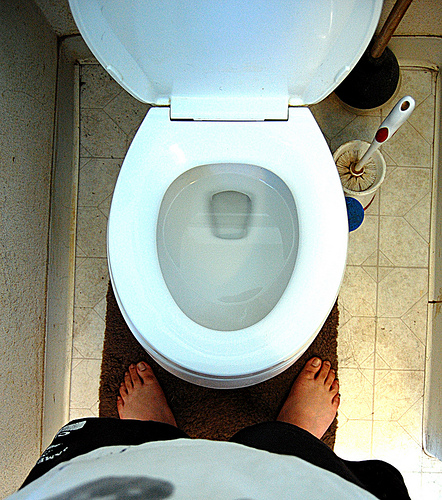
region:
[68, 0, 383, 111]
an uplifted toilet lid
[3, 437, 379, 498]
a white shirt on a person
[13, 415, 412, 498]
black shorts on a person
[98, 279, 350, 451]
a brown rug under a person's feet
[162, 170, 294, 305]
water in a toilet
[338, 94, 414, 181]
a scrub brush next to a toilet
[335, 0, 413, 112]
a plunger next to a toilet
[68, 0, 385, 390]
a white bathroom toilet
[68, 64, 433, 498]
a dirty linoleum bathroom floor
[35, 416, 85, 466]
white print on a pair of shorts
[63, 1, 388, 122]
A toilet lid is up.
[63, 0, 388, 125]
The color of a toilet lid is white.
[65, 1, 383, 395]
The color of a toilet is white.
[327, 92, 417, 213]
A brush is next to a toilet.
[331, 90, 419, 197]
The colors of a brush are white and red.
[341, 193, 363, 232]
A blue object is next to a toilet.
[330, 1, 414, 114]
A plunger is next to a toilet.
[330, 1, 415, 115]
The colors of a plunger are black and brown.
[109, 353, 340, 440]
A person's feet are visible.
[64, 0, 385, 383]
A toilet.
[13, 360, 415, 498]
A person is standing in front of the toilet.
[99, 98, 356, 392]
The toilet seat is down.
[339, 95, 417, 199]
A toilet cleaning tool on the floor.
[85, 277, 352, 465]
A brown rug on the floor.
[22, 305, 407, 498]
The person is standing on a brown rug.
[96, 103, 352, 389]
The toilet is clean.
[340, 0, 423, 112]
A plunger on the floor behind the toilet.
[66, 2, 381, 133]
The toilet cover is open.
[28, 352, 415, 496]
The person is not wearing shoes.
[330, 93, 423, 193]
red and white toilet brush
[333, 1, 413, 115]
black rubber plunger with a wooden handle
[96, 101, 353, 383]
shiny white toilet seat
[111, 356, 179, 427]
left foot of a person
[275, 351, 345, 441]
right foot f a person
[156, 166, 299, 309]
clear water in a toilet bowl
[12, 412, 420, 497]
baggy black short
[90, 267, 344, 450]
shaggy brown bathroom carpet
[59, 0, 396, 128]
shiny white toilet bowl lid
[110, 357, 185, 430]
left foot of a person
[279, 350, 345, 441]
right foot of a person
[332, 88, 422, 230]
red and white toilet bowl brush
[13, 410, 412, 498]
baggy black shorts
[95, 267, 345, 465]
shaggy brown bathroom rug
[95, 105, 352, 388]
shiny white toilet seat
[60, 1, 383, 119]
shiny white toilet seat cover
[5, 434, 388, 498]
bottom of a large white shirt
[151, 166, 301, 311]
reflective clear toilet bowl water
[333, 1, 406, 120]
black rubber plunger with a wooden handle